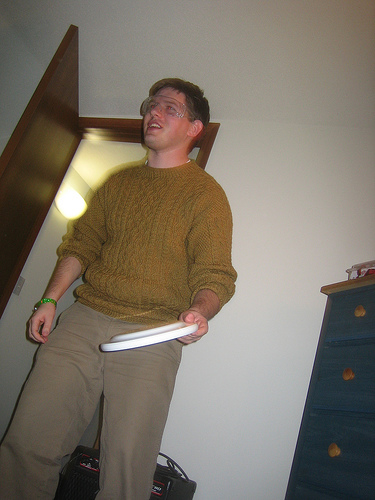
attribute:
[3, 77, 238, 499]
man — standing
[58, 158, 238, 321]
sweater — yellow, mustard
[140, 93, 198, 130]
goggles — safety goggles, clear, satety goggles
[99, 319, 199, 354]
frisbee — white, plastic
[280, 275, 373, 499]
dresser — wooden, blue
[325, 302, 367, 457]
knobs — brown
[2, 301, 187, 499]
pants — tan, long, khaki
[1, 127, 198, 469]
doorway — open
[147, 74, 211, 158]
hair — brown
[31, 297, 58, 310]
watch — bright green, wrist watch, green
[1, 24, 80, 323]
door — wooden, brown, open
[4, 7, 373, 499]
wall — white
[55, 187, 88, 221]
light — on, wall light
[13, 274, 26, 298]
switch — light switch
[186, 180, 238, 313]
sleeve — long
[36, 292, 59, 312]
wrist — right wrist